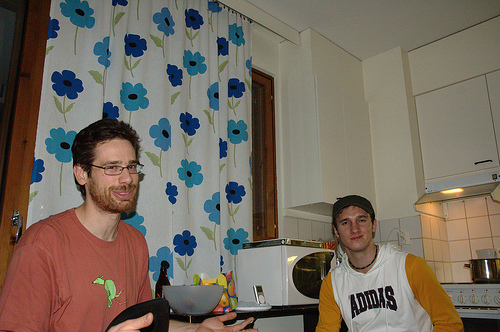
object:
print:
[121, 32, 147, 79]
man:
[312, 194, 469, 329]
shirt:
[319, 247, 462, 331]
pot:
[467, 257, 499, 283]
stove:
[437, 280, 499, 331]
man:
[2, 118, 260, 331]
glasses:
[80, 161, 142, 175]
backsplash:
[377, 203, 500, 281]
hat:
[334, 195, 374, 217]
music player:
[252, 284, 266, 304]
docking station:
[233, 301, 273, 310]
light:
[439, 186, 465, 196]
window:
[251, 69, 279, 242]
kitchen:
[2, 0, 499, 330]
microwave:
[235, 247, 335, 305]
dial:
[457, 292, 467, 303]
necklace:
[345, 246, 377, 267]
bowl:
[161, 284, 224, 315]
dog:
[92, 273, 123, 306]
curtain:
[29, 0, 254, 277]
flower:
[50, 71, 85, 119]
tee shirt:
[1, 206, 152, 330]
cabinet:
[414, 72, 498, 178]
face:
[93, 140, 139, 210]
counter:
[169, 306, 316, 331]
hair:
[71, 119, 141, 178]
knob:
[469, 294, 479, 304]